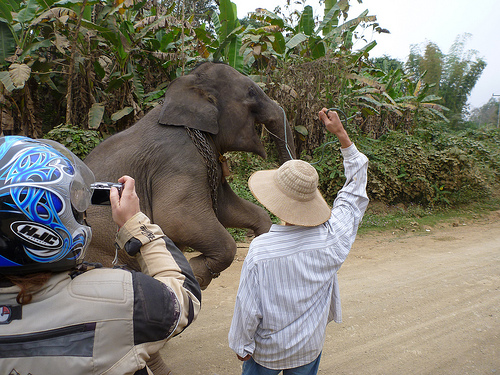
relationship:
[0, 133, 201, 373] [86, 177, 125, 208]
person has camera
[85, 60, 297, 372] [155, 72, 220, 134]
elephant has ear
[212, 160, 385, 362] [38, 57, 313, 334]
man pulls elephant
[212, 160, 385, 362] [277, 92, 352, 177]
man uses rope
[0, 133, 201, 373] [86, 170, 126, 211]
person holding camera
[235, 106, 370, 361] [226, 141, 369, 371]
man in shirt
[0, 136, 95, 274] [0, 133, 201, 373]
helmet on person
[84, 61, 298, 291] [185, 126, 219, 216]
elephant with chains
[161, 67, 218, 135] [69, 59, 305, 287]
ear on elephant